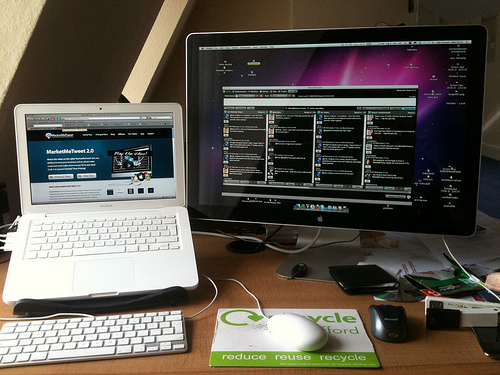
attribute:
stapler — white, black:
[424, 294, 499, 332]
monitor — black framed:
[176, 25, 492, 238]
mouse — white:
[265, 313, 326, 351]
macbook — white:
[0, 101, 199, 306]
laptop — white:
[1, 102, 198, 303]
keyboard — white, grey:
[0, 307, 191, 369]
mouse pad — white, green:
[211, 309, 256, 371]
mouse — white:
[264, 307, 328, 356]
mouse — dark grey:
[368, 302, 408, 343]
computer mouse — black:
[365, 303, 415, 347]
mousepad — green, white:
[202, 302, 385, 371]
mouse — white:
[262, 305, 334, 362]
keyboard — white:
[0, 312, 190, 371]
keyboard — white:
[25, 210, 180, 265]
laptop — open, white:
[1, 93, 206, 310]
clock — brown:
[295, 280, 340, 305]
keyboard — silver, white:
[11, 330, 172, 367]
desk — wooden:
[9, 200, 485, 369]